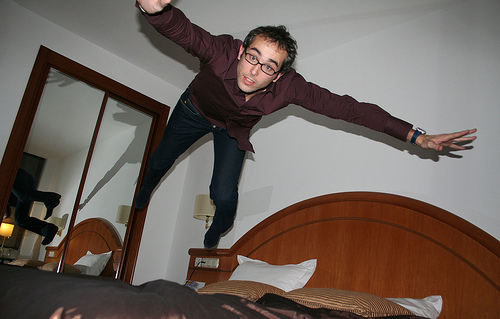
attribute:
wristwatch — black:
[406, 128, 423, 145]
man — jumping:
[126, 0, 477, 252]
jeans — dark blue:
[127, 80, 254, 240]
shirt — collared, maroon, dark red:
[138, 3, 414, 155]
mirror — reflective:
[2, 60, 154, 287]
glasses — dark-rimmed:
[238, 42, 283, 74]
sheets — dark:
[10, 259, 164, 314]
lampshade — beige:
[118, 205, 133, 227]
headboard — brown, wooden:
[183, 190, 498, 315]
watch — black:
[410, 121, 425, 151]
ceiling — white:
[74, 11, 479, 75]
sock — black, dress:
[202, 227, 220, 248]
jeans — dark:
[134, 88, 241, 235]